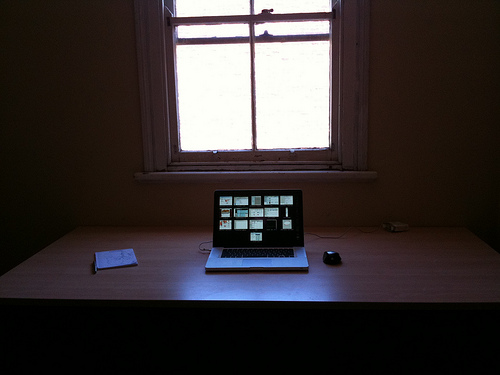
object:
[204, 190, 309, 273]
laptop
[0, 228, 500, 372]
desk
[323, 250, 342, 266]
mouse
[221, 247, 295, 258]
keyboard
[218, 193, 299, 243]
monitor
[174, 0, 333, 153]
window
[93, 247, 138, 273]
paper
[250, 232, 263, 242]
picture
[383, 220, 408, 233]
object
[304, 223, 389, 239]
cable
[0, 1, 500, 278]
wall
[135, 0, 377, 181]
sill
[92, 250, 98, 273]
pencil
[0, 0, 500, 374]
room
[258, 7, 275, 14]
latch